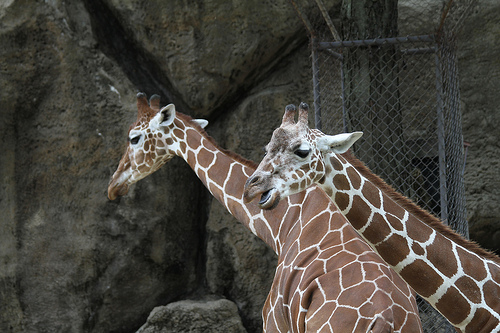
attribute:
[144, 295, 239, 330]
stone — large, gray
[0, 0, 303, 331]
stone — gray, large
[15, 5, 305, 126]
rocks — large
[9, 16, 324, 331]
rock — large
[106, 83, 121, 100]
spot — white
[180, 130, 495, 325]
necks — long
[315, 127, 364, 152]
ear — white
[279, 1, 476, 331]
chainlink fence — tall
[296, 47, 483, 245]
fence — grey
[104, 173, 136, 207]
mouth — BROWN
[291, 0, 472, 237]
silver fence — large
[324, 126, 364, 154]
ears — white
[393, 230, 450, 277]
line — solid, white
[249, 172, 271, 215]
mouth — open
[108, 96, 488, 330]
giraffes — brown, white